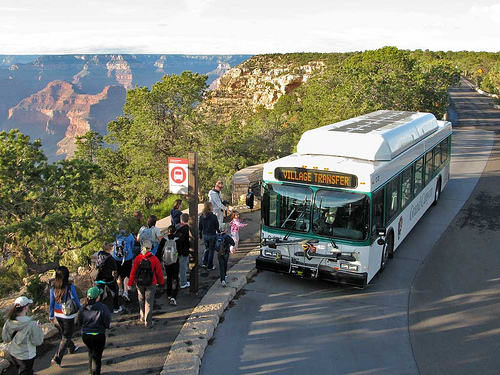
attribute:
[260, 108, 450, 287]
bus — long, white, large, green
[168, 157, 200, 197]
sign — red, white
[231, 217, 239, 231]
girl's shirt — pink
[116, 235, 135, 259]
woman's shirt — blue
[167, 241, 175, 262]
backpack — grey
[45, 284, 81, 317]
shirt — blue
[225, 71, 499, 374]
road — paved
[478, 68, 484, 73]
street sign — yellow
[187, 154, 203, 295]
pole — tall, wooden